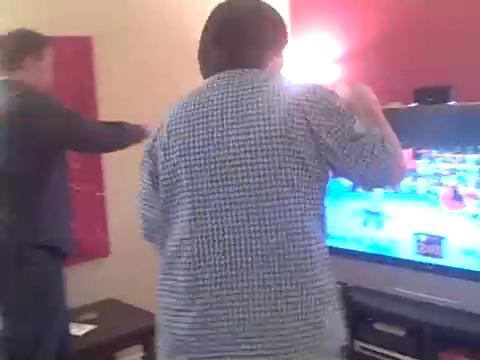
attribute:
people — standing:
[8, 31, 349, 273]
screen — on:
[385, 127, 474, 236]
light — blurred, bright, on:
[278, 23, 362, 107]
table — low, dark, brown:
[77, 294, 148, 327]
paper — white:
[74, 315, 113, 345]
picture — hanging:
[62, 32, 100, 92]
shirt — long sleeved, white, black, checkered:
[183, 109, 291, 210]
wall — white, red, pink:
[370, 18, 471, 70]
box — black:
[360, 313, 421, 357]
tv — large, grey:
[348, 229, 460, 286]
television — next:
[342, 100, 477, 253]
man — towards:
[126, 20, 324, 258]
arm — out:
[62, 102, 161, 156]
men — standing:
[7, 34, 424, 349]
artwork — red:
[49, 20, 147, 300]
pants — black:
[5, 251, 84, 350]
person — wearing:
[138, 26, 349, 336]